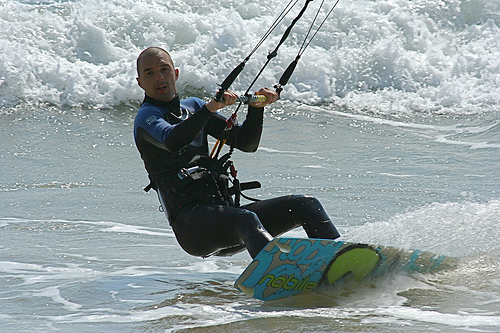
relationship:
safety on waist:
[143, 146, 253, 209] [142, 155, 252, 211]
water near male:
[4, 97, 499, 329] [133, 44, 339, 256]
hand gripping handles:
[208, 90, 244, 112] [235, 92, 243, 102]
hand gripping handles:
[251, 88, 277, 105] [252, 91, 268, 101]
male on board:
[133, 44, 339, 256] [232, 238, 476, 299]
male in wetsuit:
[133, 44, 339, 256] [122, 98, 342, 255]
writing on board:
[263, 274, 321, 296] [241, 226, 379, 307]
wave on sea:
[1, 25, 134, 121] [15, 15, 500, 305]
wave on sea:
[60, 265, 229, 297] [0, 0, 499, 331]